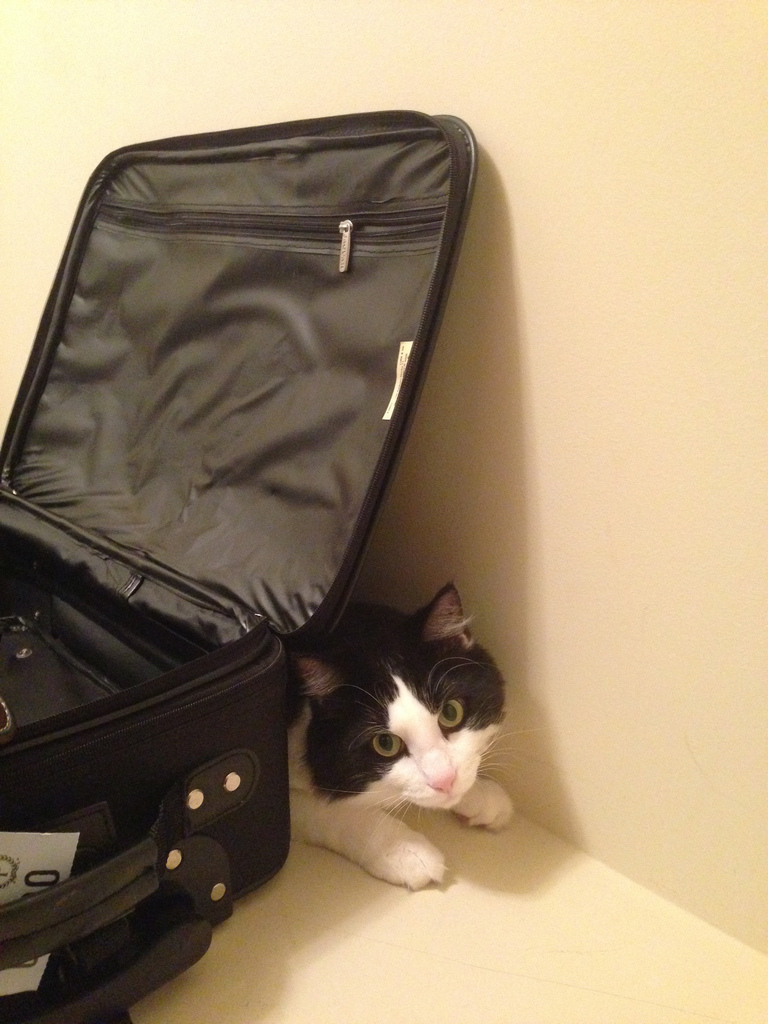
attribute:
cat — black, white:
[293, 557, 614, 975]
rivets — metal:
[170, 730, 260, 858]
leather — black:
[80, 164, 363, 663]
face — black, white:
[338, 589, 527, 840]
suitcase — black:
[15, 149, 442, 1018]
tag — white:
[353, 300, 473, 468]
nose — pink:
[401, 713, 505, 845]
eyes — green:
[339, 684, 545, 806]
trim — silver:
[137, 759, 318, 923]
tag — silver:
[339, 272, 431, 422]